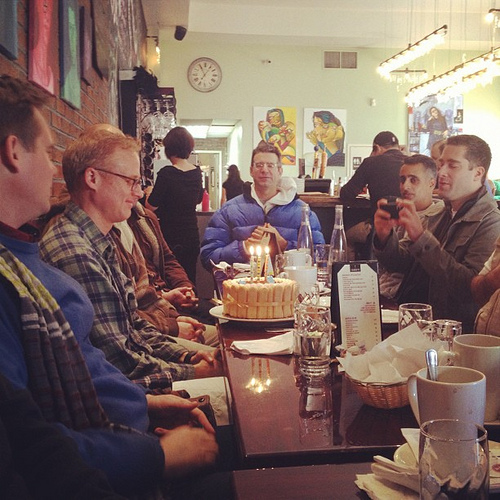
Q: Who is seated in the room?
A: A group of men.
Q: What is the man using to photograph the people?
A: A camera.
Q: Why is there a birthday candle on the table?
A: The men are celebrating someone's birthday.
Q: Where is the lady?
A: Behind the men.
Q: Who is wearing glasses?
A: The man being photographed.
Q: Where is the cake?
A: On the table.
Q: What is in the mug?
A: A spoon.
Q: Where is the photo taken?
A: Restaurant.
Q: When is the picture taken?
A: Daytime.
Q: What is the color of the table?
A: Brown.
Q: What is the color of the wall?
A: Green.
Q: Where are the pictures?
A: In the wall.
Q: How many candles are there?
A: 3.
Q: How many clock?
A: 1.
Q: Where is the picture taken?
A: At a restaurant.